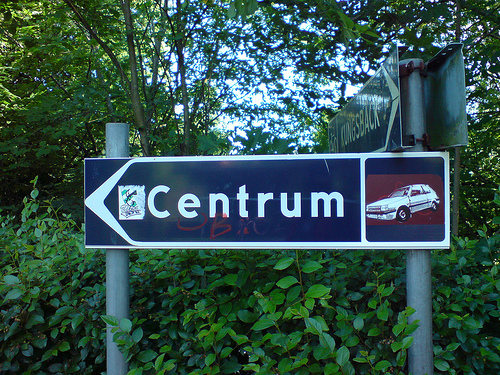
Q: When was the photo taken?
A: Daylight hours.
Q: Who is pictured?
A: No one.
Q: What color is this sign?
A: Blue.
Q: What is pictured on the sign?
A: A car.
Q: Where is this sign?
A: In front of trees.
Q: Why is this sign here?
A: To direct people.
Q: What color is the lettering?
A: White.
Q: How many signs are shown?
A: 3.